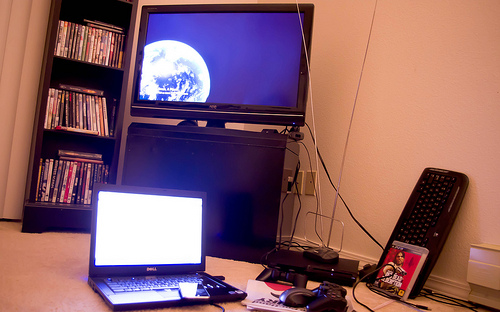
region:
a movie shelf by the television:
[10, 0, 145, 234]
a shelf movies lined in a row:
[33, 10, 133, 78]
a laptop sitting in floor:
[79, 175, 259, 307]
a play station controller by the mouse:
[296, 274, 353, 310]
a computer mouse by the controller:
[272, 284, 327, 309]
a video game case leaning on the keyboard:
[364, 231, 435, 307]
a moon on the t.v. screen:
[128, 27, 221, 108]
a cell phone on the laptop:
[172, 273, 214, 304]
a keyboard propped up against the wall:
[356, 150, 473, 310]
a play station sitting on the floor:
[256, 239, 363, 294]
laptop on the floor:
[58, 164, 243, 309]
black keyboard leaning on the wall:
[347, 165, 479, 310]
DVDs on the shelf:
[26, 0, 155, 260]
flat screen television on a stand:
[133, 6, 322, 133]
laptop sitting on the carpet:
[78, 182, 248, 302]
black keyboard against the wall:
[362, 138, 472, 301]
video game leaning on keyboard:
[370, 232, 425, 299]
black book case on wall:
[40, 6, 114, 239]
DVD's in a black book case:
[32, 2, 119, 242]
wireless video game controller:
[307, 275, 356, 310]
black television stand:
[115, 115, 300, 250]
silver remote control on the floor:
[245, 286, 311, 310]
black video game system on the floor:
[262, 233, 373, 292]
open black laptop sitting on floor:
[86, 178, 235, 305]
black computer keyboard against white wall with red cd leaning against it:
[369, 152, 481, 297]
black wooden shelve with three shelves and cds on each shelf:
[17, 0, 144, 238]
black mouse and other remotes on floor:
[262, 278, 350, 308]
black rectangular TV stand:
[118, 120, 308, 261]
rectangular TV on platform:
[126, 1, 321, 121]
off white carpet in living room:
[9, 205, 499, 307]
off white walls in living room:
[8, 0, 495, 300]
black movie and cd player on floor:
[263, 241, 371, 283]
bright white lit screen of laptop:
[94, 199, 197, 263]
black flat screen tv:
[138, 8, 317, 125]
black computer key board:
[371, 167, 473, 294]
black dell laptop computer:
[87, 183, 247, 304]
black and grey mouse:
[275, 283, 313, 305]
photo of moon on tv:
[138, 36, 217, 103]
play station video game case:
[377, 235, 427, 300]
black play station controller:
[308, 270, 344, 310]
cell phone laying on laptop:
[174, 275, 211, 302]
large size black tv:
[138, 5, 308, 129]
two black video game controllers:
[250, 261, 355, 309]